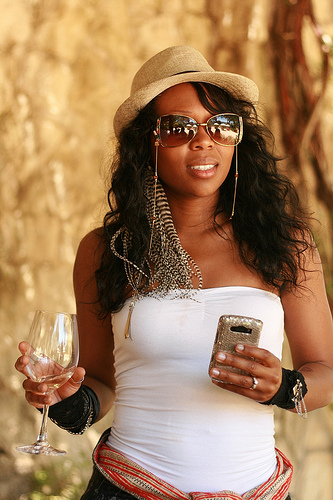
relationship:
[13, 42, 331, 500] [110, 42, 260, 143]
woman wearing hat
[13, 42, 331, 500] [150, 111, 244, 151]
woman wearing sunglasses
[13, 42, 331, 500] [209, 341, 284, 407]
woman has left hand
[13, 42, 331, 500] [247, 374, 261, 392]
woman wearing ring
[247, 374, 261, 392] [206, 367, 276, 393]
ring on finger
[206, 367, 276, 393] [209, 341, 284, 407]
finger on left hand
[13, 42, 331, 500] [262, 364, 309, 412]
woman wears wristband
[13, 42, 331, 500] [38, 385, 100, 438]
woman wears wristband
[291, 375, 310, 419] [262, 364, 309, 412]
detail on wristband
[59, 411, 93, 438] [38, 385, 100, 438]
detail on wristband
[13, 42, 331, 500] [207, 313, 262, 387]
woman holds cell phone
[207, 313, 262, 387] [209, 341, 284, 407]
cell phone in left hand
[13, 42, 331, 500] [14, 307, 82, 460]
woman holds wine glass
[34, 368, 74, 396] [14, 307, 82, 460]
liquid in wine glass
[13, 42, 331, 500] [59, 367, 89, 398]
woman has right thumb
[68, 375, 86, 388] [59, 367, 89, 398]
ring on right thumb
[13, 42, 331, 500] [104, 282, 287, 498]
woman wears tube top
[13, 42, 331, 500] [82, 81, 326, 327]
woman has hair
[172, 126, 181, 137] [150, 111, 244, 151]
person reflected in sunglasses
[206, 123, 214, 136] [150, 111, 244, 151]
person reflected in sunglasses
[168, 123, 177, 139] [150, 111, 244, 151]
person reflected in sunglasses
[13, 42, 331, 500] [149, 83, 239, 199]
woman has face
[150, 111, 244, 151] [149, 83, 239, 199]
sunglasses are on face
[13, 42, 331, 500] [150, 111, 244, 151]
woman has sunglasses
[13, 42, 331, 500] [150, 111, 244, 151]
woman wears sunglasses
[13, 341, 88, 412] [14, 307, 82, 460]
hand holding wine glass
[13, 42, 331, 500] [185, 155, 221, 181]
woman has mouth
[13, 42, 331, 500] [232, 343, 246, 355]
woman has fingernail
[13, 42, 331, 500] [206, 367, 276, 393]
woman has finger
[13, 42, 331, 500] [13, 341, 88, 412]
woman has hand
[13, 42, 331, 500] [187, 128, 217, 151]
woman has nose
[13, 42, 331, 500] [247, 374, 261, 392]
woman wears ring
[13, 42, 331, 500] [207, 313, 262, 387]
woman has cell phone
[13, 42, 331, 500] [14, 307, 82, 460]
woman holding wine glass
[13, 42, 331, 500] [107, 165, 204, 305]
woman wears feathers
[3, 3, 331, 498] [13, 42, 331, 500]
wall behind woman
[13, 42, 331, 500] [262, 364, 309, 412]
woman has wristband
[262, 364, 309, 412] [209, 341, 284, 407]
wristband above left hand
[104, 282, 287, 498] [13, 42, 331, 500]
tube top on woman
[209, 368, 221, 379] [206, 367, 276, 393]
fingernail on finger